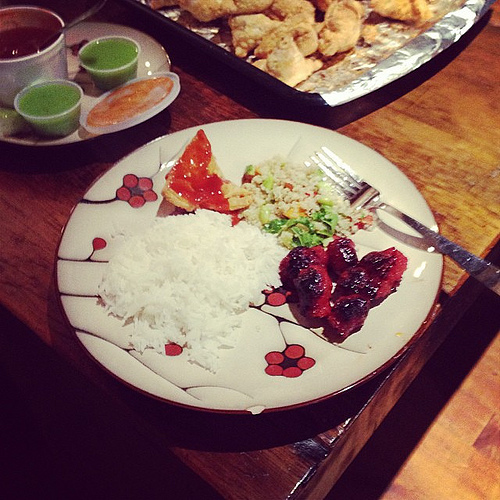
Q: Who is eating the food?
A: No one.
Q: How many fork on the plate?
A: One.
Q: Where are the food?
A: On the table.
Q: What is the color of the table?
A: Brown.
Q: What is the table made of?
A: Wood.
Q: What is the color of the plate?
A: White, red and black.